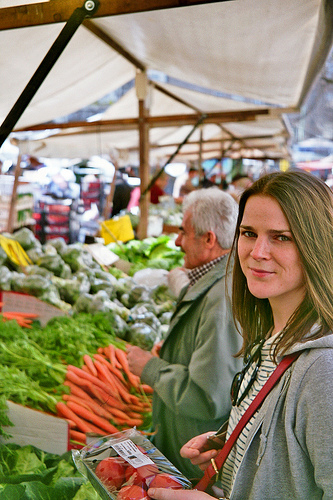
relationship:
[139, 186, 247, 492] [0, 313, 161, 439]
man laughing at salad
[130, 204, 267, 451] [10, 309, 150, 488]
man laughing at vegetables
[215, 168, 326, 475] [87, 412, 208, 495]
young woman holding tomatoes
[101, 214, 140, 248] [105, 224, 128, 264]
paper taped to sticks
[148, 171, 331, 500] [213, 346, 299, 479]
woman wearing shirt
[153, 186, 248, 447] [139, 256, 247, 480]
man wearing jacket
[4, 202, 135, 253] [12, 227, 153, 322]
signs among produce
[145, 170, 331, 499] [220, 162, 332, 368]
woman with hair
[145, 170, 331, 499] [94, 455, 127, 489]
woman holding tomato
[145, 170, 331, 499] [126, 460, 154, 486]
woman holding tomato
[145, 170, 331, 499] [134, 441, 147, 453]
woman holding tomato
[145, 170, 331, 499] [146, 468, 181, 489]
woman holding tomato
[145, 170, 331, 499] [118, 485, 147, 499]
woman holding tomato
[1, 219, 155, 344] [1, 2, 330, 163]
produce shaded by umbrellas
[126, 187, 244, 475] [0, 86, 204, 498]
person at market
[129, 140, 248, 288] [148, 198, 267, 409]
head on person